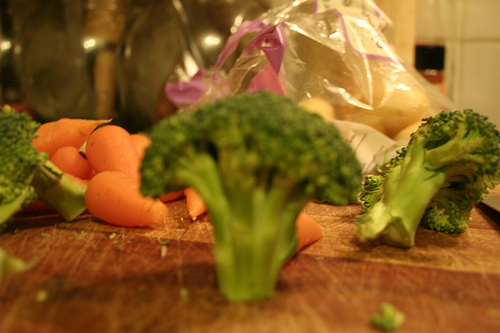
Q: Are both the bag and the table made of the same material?
A: No, the bag is made of plastic and the table is made of wood.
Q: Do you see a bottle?
A: Yes, there is a bottle.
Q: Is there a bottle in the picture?
A: Yes, there is a bottle.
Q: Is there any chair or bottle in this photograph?
A: Yes, there is a bottle.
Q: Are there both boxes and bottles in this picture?
A: No, there is a bottle but no boxes.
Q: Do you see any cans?
A: No, there are no cans.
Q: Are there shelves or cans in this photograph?
A: No, there are no cans or shelves.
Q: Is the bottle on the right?
A: Yes, the bottle is on the right of the image.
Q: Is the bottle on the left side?
A: No, the bottle is on the right of the image.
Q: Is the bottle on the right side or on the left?
A: The bottle is on the right of the image.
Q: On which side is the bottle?
A: The bottle is on the right of the image.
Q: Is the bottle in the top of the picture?
A: Yes, the bottle is in the top of the image.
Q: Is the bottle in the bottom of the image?
A: No, the bottle is in the top of the image.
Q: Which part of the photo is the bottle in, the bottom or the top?
A: The bottle is in the top of the image.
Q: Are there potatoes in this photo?
A: Yes, there is a potato.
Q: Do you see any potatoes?
A: Yes, there is a potato.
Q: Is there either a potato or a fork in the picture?
A: Yes, there is a potato.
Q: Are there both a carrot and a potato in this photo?
A: Yes, there are both a potato and a carrot.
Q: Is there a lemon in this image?
A: No, there are no lemons.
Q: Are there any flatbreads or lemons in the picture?
A: No, there are no lemons or flatbreads.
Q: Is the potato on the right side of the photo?
A: Yes, the potato is on the right of the image.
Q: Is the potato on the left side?
A: No, the potato is on the right of the image.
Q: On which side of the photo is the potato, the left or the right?
A: The potato is on the right of the image.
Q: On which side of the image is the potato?
A: The potato is on the right of the image.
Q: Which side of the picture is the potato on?
A: The potato is on the right of the image.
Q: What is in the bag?
A: The potato is in the bag.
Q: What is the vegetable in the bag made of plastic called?
A: The vegetable is a potato.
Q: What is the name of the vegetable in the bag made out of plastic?
A: The vegetable is a potato.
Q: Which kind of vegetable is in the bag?
A: The vegetable is a potato.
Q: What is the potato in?
A: The potato is in the bag.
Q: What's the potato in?
A: The potato is in the bag.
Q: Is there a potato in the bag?
A: Yes, there is a potato in the bag.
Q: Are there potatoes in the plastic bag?
A: Yes, there is a potato in the bag.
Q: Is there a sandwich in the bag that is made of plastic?
A: No, there is a potato in the bag.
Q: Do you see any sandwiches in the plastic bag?
A: No, there is a potato in the bag.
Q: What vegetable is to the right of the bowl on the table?
A: The vegetable is a potato.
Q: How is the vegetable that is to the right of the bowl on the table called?
A: The vegetable is a potato.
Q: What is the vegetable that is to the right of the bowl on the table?
A: The vegetable is a potato.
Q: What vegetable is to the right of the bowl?
A: The vegetable is a potato.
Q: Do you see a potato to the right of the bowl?
A: Yes, there is a potato to the right of the bowl.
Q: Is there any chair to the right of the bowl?
A: No, there is a potato to the right of the bowl.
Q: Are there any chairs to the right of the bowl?
A: No, there is a potato to the right of the bowl.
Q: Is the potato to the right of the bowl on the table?
A: Yes, the potato is to the right of the bowl.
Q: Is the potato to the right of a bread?
A: No, the potato is to the right of the bowl.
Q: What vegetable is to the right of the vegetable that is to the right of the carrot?
A: The vegetable is a potato.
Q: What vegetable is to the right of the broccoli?
A: The vegetable is a potato.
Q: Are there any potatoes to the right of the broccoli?
A: Yes, there is a potato to the right of the broccoli.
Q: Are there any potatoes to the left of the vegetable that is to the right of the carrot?
A: No, the potato is to the right of the broccoli.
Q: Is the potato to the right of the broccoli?
A: Yes, the potato is to the right of the broccoli.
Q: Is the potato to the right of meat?
A: No, the potato is to the right of the broccoli.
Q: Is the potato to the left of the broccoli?
A: No, the potato is to the right of the broccoli.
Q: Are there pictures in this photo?
A: No, there are no pictures.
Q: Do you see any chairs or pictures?
A: No, there are no pictures or chairs.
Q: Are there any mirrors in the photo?
A: No, there are no mirrors.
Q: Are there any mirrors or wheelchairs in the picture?
A: No, there are no mirrors or wheelchairs.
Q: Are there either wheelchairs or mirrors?
A: No, there are no mirrors or wheelchairs.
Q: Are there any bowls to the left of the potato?
A: Yes, there is a bowl to the left of the potato.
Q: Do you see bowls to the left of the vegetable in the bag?
A: Yes, there is a bowl to the left of the potato.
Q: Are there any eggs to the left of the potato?
A: No, there is a bowl to the left of the potato.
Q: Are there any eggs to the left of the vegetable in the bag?
A: No, there is a bowl to the left of the potato.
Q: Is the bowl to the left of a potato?
A: Yes, the bowl is to the left of a potato.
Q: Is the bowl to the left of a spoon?
A: No, the bowl is to the left of a potato.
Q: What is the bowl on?
A: The bowl is on the table.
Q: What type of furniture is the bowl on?
A: The bowl is on the table.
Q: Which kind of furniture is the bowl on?
A: The bowl is on the table.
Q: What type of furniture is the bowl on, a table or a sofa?
A: The bowl is on a table.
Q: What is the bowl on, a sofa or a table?
A: The bowl is on a table.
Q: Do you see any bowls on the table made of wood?
A: Yes, there is a bowl on the table.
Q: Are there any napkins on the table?
A: No, there is a bowl on the table.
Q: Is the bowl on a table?
A: Yes, the bowl is on a table.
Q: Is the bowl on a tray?
A: No, the bowl is on a table.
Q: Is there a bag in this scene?
A: Yes, there is a bag.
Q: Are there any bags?
A: Yes, there is a bag.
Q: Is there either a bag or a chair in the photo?
A: Yes, there is a bag.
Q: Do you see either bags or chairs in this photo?
A: Yes, there is a bag.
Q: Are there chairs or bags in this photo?
A: Yes, there is a bag.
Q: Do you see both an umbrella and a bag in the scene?
A: No, there is a bag but no umbrellas.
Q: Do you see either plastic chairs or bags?
A: Yes, there is a plastic bag.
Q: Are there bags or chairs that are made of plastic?
A: Yes, the bag is made of plastic.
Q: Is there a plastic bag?
A: Yes, there is a bag that is made of plastic.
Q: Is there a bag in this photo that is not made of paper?
A: Yes, there is a bag that is made of plastic.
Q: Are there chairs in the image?
A: No, there are no chairs.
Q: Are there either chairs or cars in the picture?
A: No, there are no chairs or cars.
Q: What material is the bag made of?
A: The bag is made of plastic.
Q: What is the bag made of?
A: The bag is made of plastic.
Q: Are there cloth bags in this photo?
A: No, there is a bag but it is made of plastic.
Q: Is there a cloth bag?
A: No, there is a bag but it is made of plastic.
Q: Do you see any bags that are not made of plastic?
A: No, there is a bag but it is made of plastic.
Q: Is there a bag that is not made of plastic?
A: No, there is a bag but it is made of plastic.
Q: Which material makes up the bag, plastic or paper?
A: The bag is made of plastic.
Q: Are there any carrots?
A: Yes, there is a carrot.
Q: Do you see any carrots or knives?
A: Yes, there is a carrot.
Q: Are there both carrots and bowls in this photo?
A: Yes, there are both a carrot and a bowl.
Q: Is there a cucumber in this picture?
A: No, there are no cucumbers.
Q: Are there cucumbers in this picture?
A: No, there are no cucumbers.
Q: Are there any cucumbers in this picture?
A: No, there are no cucumbers.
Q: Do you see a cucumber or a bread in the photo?
A: No, there are no cucumbers or breads.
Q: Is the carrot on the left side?
A: Yes, the carrot is on the left of the image.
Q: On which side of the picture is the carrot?
A: The carrot is on the left of the image.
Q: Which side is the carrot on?
A: The carrot is on the left of the image.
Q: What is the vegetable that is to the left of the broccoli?
A: The vegetable is a carrot.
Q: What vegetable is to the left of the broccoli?
A: The vegetable is a carrot.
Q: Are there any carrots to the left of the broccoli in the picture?
A: Yes, there is a carrot to the left of the broccoli.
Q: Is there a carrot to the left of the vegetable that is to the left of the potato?
A: Yes, there is a carrot to the left of the broccoli.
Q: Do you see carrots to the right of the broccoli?
A: No, the carrot is to the left of the broccoli.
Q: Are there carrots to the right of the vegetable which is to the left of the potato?
A: No, the carrot is to the left of the broccoli.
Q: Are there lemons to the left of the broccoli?
A: No, there is a carrot to the left of the broccoli.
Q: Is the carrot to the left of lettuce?
A: No, the carrot is to the left of the broccoli.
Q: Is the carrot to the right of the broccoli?
A: No, the carrot is to the left of the broccoli.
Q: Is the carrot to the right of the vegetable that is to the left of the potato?
A: No, the carrot is to the left of the broccoli.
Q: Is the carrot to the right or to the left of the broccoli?
A: The carrot is to the left of the broccoli.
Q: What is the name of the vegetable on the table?
A: The vegetable is a carrot.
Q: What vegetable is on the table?
A: The vegetable is a carrot.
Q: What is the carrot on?
A: The carrot is on the table.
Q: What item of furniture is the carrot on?
A: The carrot is on the table.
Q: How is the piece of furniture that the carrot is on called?
A: The piece of furniture is a table.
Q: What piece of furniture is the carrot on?
A: The carrot is on the table.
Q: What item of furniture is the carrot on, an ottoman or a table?
A: The carrot is on a table.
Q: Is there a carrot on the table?
A: Yes, there is a carrot on the table.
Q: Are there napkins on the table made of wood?
A: No, there is a carrot on the table.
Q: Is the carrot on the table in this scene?
A: Yes, the carrot is on the table.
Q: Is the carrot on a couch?
A: No, the carrot is on the table.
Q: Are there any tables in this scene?
A: Yes, there is a table.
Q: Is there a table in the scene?
A: Yes, there is a table.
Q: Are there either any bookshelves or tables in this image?
A: Yes, there is a table.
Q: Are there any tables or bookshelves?
A: Yes, there is a table.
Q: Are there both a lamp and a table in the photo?
A: No, there is a table but no lamps.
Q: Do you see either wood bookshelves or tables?
A: Yes, there is a wood table.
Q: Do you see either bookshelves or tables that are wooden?
A: Yes, the table is wooden.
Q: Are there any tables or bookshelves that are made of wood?
A: Yes, the table is made of wood.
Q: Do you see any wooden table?
A: Yes, there is a wood table.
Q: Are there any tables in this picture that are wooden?
A: Yes, there is a table that is wooden.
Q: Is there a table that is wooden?
A: Yes, there is a table that is wooden.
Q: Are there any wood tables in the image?
A: Yes, there is a table that is made of wood.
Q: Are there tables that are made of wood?
A: Yes, there is a table that is made of wood.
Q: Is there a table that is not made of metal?
A: Yes, there is a table that is made of wood.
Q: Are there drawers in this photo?
A: No, there are no drawers.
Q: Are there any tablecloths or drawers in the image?
A: No, there are no drawers or tablecloths.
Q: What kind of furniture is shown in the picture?
A: The furniture is a table.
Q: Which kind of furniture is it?
A: The piece of furniture is a table.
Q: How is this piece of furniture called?
A: This is a table.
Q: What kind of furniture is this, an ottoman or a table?
A: This is a table.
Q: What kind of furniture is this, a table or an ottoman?
A: This is a table.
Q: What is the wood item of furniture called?
A: The piece of furniture is a table.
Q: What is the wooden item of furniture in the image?
A: The piece of furniture is a table.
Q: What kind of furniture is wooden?
A: The furniture is a table.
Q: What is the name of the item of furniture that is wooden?
A: The piece of furniture is a table.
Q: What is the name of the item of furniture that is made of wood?
A: The piece of furniture is a table.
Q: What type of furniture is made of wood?
A: The furniture is a table.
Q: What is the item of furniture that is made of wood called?
A: The piece of furniture is a table.